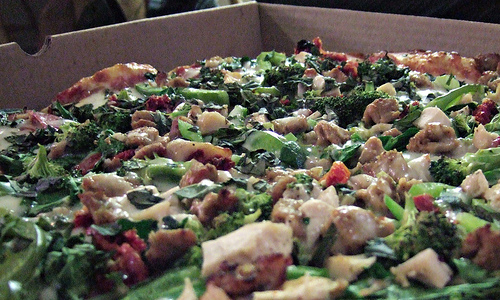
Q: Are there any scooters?
A: No, there are no scooters.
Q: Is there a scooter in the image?
A: No, there are no scooters.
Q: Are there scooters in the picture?
A: No, there are no scooters.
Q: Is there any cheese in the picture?
A: Yes, there is cheese.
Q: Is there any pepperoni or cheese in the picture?
A: Yes, there is cheese.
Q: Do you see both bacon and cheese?
A: No, there is cheese but no bacon.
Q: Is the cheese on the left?
A: No, the cheese is on the right of the image.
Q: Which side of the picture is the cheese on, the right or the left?
A: The cheese is on the right of the image.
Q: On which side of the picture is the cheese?
A: The cheese is on the right of the image.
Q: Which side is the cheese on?
A: The cheese is on the right of the image.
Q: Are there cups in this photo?
A: No, there are no cups.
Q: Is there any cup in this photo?
A: No, there are no cups.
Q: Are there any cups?
A: No, there are no cups.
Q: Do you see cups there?
A: No, there are no cups.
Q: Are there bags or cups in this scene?
A: No, there are no cups or bags.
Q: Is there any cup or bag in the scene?
A: No, there are no cups or bags.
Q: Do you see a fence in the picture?
A: No, there are no fences.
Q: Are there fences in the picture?
A: No, there are no fences.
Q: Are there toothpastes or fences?
A: No, there are no fences or toothpastes.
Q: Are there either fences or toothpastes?
A: No, there are no fences or toothpastes.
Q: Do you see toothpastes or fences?
A: No, there are no fences or toothpastes.